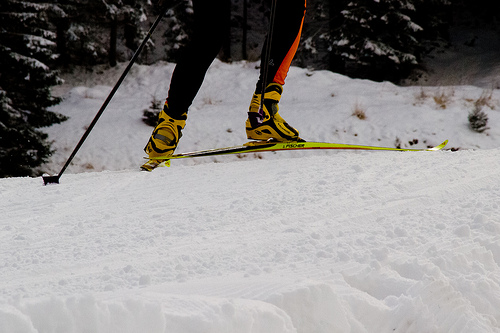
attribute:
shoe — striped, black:
[243, 90, 294, 154]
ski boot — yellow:
[243, 78, 300, 143]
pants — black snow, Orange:
[162, 0, 312, 117]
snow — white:
[30, 34, 49, 43]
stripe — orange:
[273, 6, 319, 98]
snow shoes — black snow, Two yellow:
[138, 97, 312, 154]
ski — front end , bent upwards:
[432, 134, 458, 154]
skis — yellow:
[153, 137, 459, 157]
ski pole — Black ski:
[48, 85, 118, 181]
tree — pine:
[301, 0, 420, 78]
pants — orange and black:
[256, 5, 309, 75]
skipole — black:
[61, 105, 121, 178]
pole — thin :
[39, 0, 174, 184]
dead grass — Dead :
[408, 90, 497, 115]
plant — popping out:
[416, 78, 430, 105]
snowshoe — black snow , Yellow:
[246, 90, 302, 144]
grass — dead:
[416, 81, 428, 101]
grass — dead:
[431, 85, 449, 108]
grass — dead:
[444, 82, 455, 96]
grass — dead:
[473, 87, 485, 110]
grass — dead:
[484, 79, 495, 109]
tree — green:
[1, 0, 86, 211]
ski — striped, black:
[171, 126, 381, 171]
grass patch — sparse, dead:
[406, 80, 491, 134]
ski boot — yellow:
[142, 100, 197, 160]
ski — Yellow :
[151, 133, 455, 173]